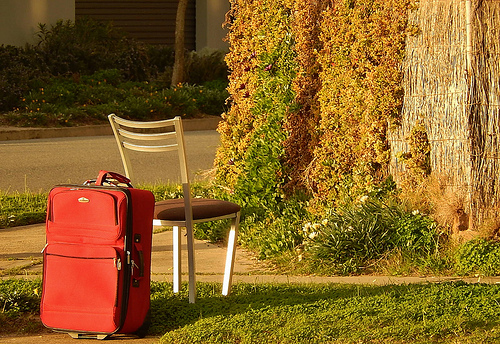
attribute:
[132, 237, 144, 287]
handle — black , red 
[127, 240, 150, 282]
handle — side   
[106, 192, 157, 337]
zippers — silver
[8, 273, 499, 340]
grass — green   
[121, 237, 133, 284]
zipper — Silver 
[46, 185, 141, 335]
suitcase — red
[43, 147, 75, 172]
pavement — cement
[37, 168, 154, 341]
suitcase — red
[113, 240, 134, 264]
zipper — silver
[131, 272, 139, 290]
button — Small silver 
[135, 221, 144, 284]
handle — red  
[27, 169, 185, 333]
suitcase — closed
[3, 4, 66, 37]
wall — brown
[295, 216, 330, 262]
flowers — white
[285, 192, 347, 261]
flowers — white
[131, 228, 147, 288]
handle — red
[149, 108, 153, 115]
flower — orange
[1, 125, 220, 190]
road — empty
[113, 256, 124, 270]
zipper — Silver 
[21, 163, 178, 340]
suitcase — Red 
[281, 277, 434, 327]
grass — green 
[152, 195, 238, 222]
cushion — Brown 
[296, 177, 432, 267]
flowers — white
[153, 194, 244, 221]
cushion — chair , brown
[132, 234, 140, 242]
button — Small silver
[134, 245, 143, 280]
handle — red 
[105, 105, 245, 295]
chair — silver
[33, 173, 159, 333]
suitcase — red , behind, side   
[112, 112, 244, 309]
chair — white, brown,  behind 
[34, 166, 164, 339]
suitcase — red